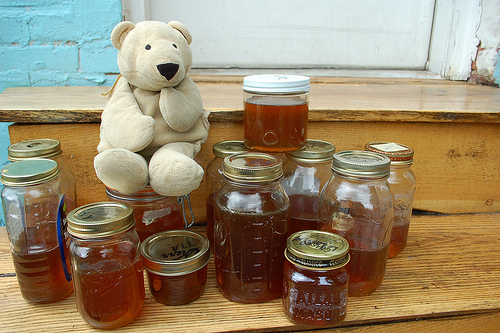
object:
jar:
[101, 176, 186, 244]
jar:
[210, 150, 291, 304]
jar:
[242, 73, 309, 151]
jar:
[66, 200, 143, 330]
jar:
[138, 229, 211, 306]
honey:
[243, 94, 308, 153]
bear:
[93, 20, 210, 197]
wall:
[386, 151, 422, 193]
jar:
[1, 156, 73, 304]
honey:
[12, 225, 75, 303]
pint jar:
[285, 230, 351, 326]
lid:
[243, 74, 312, 94]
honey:
[209, 186, 287, 306]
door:
[142, 1, 439, 70]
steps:
[309, 80, 500, 142]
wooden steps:
[0, 61, 499, 330]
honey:
[147, 264, 208, 306]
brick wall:
[0, 1, 122, 228]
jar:
[318, 151, 399, 298]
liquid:
[282, 262, 348, 328]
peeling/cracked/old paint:
[430, 0, 499, 87]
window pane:
[208, 29, 428, 69]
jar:
[284, 228, 352, 328]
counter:
[1, 82, 499, 332]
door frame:
[427, 0, 481, 84]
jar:
[364, 140, 416, 259]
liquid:
[388, 215, 410, 258]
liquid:
[348, 245, 388, 298]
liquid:
[214, 192, 291, 304]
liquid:
[244, 96, 309, 153]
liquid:
[68, 241, 146, 328]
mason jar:
[283, 230, 351, 325]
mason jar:
[214, 151, 292, 303]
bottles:
[1, 74, 418, 329]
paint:
[3, 0, 123, 227]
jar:
[215, 154, 293, 302]